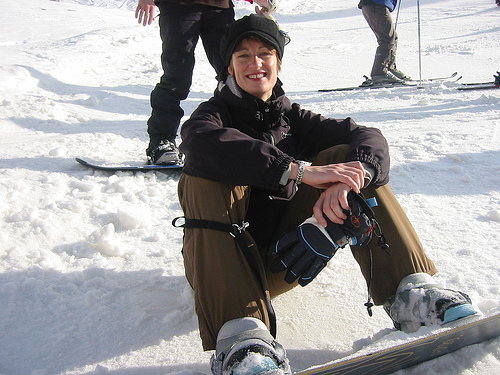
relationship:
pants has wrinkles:
[164, 168, 462, 319] [386, 229, 444, 280]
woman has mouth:
[167, 14, 400, 371] [238, 71, 273, 89]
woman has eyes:
[167, 14, 400, 371] [215, 45, 286, 67]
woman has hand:
[167, 14, 400, 371] [280, 152, 362, 188]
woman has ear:
[167, 14, 400, 371] [225, 57, 235, 78]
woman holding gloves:
[167, 14, 482, 372] [261, 179, 384, 292]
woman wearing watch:
[167, 14, 482, 372] [282, 152, 313, 195]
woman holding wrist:
[167, 14, 482, 372] [302, 161, 380, 239]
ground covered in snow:
[6, 7, 478, 373] [1, 128, 299, 371]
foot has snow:
[210, 323, 290, 373] [235, 351, 271, 371]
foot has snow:
[382, 276, 476, 333] [397, 285, 451, 320]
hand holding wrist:
[306, 155, 366, 194] [302, 161, 380, 239]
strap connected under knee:
[158, 199, 299, 315] [175, 176, 226, 197]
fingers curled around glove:
[312, 190, 352, 226] [262, 211, 347, 290]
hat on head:
[200, 4, 307, 80] [210, 11, 288, 69]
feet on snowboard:
[189, 280, 499, 373] [295, 290, 483, 373]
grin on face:
[241, 69, 272, 84] [214, 17, 295, 90]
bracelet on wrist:
[283, 143, 313, 191] [289, 162, 311, 182]